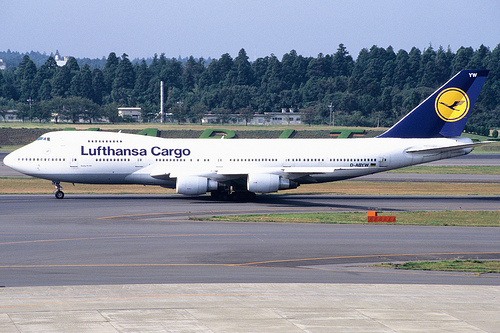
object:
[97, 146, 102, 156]
letter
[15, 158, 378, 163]
row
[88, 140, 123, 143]
row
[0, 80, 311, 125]
buildings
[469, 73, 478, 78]
yw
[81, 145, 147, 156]
text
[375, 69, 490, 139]
graphic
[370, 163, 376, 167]
flag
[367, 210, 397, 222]
object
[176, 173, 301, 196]
engines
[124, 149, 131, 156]
blue letter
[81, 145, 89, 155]
letter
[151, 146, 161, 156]
letter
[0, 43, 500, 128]
trees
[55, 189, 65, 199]
wheel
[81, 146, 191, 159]
letters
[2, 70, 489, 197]
plane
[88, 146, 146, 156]
letter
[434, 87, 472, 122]
logo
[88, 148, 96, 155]
letter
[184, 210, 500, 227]
grass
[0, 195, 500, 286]
runway